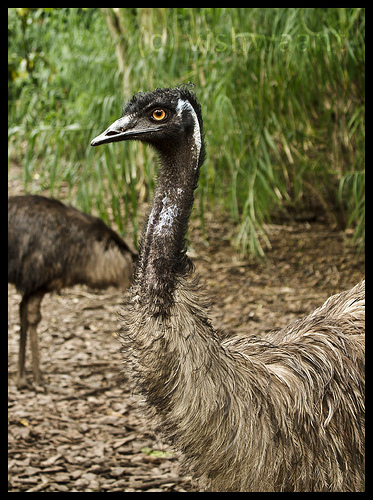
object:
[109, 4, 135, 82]
branch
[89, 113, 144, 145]
beak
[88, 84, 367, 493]
bird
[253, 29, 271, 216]
branch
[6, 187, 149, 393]
bird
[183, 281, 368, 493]
brown feathers